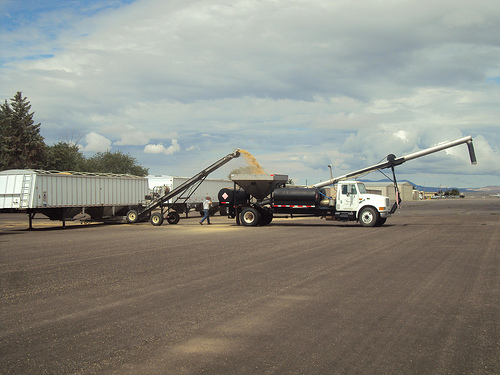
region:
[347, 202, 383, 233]
front wheels of the truck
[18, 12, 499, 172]
huge cloud in the sky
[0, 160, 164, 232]
large white section of the vehicle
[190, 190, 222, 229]
person is walking toward the truck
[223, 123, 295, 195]
sand is emptying into the truck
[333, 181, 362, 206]
side window of the truck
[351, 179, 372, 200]
front window of the truck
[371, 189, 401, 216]
front lights of the truck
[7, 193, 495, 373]
road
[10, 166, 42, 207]
ladder on the white vehicle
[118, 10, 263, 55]
this is the cloud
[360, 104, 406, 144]
the claud id white in color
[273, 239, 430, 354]
this is a road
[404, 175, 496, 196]
this is a mountain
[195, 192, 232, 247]
this is a person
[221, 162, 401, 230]
this is a truck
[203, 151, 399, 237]
the truck is being loaded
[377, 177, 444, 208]
these are buildings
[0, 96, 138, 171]
these are trees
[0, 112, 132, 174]
the trees are green in color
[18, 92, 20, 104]
top part of atree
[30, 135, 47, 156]
leaves of a tree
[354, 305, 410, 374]
section of a road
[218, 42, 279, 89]
section of white clouds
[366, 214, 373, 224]
front wheel of a truck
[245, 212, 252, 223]
back wheel of a truck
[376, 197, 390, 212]
front part of atruck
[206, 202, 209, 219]
section of man's body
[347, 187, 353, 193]
section of truck's window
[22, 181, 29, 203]
ladder of a trailer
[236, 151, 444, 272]
the track is carrying sand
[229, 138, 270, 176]
the sand is in the air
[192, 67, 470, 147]
the sky is cloudy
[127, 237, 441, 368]
the tarmac is grey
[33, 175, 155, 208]
the lorry is white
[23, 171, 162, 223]
the lorry is mettalic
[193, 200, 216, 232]
the man has blue pants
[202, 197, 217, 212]
the shirt is white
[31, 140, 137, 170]
the trees are green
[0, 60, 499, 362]
the photo was taken out doors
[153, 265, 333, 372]
this is a road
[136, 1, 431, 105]
this is the sky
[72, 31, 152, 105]
these are some clouds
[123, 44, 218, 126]
the clouds are white in color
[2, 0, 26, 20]
the sky is blue in color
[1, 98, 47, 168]
this is a tree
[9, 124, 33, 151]
the leaves are green in color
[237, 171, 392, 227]
this is a truck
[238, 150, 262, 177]
this is a lot of sand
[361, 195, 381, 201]
the truck is white in color